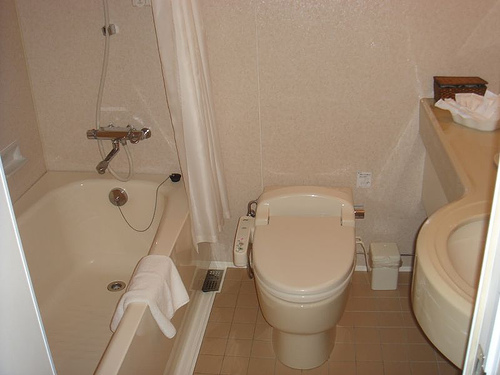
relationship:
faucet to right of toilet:
[85, 122, 150, 175] [229, 183, 364, 366]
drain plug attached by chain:
[169, 173, 181, 182] [109, 174, 168, 234]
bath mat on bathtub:
[108, 251, 190, 338] [13, 171, 204, 373]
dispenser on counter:
[437, 90, 484, 124] [400, 94, 483, 366]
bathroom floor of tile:
[190, 271, 461, 375] [188, 264, 456, 370]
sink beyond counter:
[405, 195, 485, 365] [406, 92, 485, 367]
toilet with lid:
[229, 183, 364, 366] [250, 215, 356, 291]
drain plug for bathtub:
[169, 173, 181, 182] [13, 171, 204, 373]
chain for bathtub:
[114, 173, 174, 233] [13, 171, 204, 373]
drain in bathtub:
[107, 280, 126, 293] [13, 171, 204, 373]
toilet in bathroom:
[229, 183, 364, 366] [8, 7, 484, 368]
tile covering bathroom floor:
[204, 302, 238, 322] [190, 271, 461, 375]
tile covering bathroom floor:
[228, 303, 259, 323] [190, 271, 461, 375]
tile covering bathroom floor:
[352, 324, 381, 343] [190, 271, 461, 375]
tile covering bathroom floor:
[380, 342, 410, 361] [190, 271, 461, 375]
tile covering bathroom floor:
[376, 308, 405, 327] [190, 271, 461, 375]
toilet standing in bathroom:
[229, 183, 364, 366] [0, 0, 500, 375]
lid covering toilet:
[249, 210, 357, 295] [229, 183, 364, 366]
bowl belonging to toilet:
[251, 276, 354, 333] [229, 183, 364, 366]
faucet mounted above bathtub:
[85, 122, 150, 174] [12, 168, 214, 373]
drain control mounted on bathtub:
[107, 185, 129, 206] [12, 168, 214, 373]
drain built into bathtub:
[107, 280, 126, 293] [12, 168, 214, 373]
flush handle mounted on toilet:
[352, 201, 364, 220] [229, 183, 364, 366]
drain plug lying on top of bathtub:
[167, 170, 181, 183] [12, 168, 214, 373]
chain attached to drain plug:
[114, 173, 174, 233] [168, 171, 181, 181]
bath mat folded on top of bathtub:
[108, 251, 190, 338] [12, 168, 214, 373]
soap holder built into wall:
[2, 138, 30, 178] [2, 1, 48, 205]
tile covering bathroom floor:
[222, 335, 256, 355] [190, 266, 461, 373]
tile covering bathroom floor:
[248, 335, 279, 359] [190, 266, 461, 373]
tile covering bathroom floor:
[353, 340, 383, 363] [190, 266, 461, 373]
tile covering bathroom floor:
[380, 341, 407, 360] [190, 266, 461, 373]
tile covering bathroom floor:
[407, 342, 437, 362] [190, 266, 461, 373]